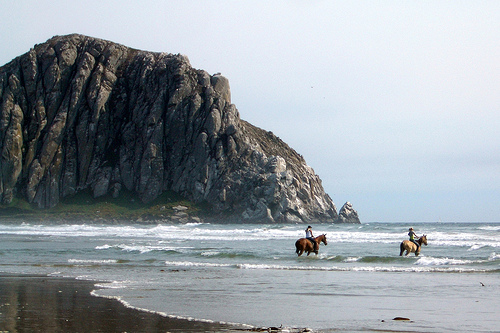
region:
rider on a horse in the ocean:
[294, 226, 326, 257]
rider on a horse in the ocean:
[398, 228, 430, 258]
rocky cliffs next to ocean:
[1, 32, 362, 221]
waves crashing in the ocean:
[11, 222, 496, 244]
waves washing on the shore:
[1, 259, 491, 331]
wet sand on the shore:
[1, 272, 278, 332]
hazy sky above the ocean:
[0, 1, 497, 223]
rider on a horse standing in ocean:
[293, 225, 328, 257]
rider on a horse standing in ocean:
[399, 226, 429, 257]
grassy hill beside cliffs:
[2, 189, 222, 226]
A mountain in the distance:
[0, 33, 361, 227]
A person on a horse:
[295, 225, 327, 257]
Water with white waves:
[0, 223, 499, 332]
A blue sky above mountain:
[0, 0, 499, 220]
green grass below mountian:
[0, 180, 208, 221]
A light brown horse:
[397, 233, 429, 256]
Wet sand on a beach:
[0, 276, 251, 332]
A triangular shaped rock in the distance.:
[339, 201, 359, 224]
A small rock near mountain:
[172, 203, 189, 211]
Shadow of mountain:
[63, 175, 185, 210]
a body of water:
[167, 188, 490, 290]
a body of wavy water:
[168, 222, 492, 325]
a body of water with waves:
[248, 231, 417, 299]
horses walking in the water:
[261, 190, 480, 330]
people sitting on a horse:
[289, 211, 483, 281]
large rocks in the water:
[118, 9, 417, 308]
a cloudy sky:
[312, 33, 466, 155]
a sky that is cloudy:
[326, 37, 496, 201]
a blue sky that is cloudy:
[304, 60, 496, 175]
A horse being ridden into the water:
[294, 223, 327, 256]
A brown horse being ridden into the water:
[397, 225, 429, 255]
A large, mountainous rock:
[2, 33, 363, 224]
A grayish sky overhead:
[3, 1, 497, 223]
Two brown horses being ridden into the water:
[294, 222, 428, 258]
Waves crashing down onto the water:
[13, 215, 495, 274]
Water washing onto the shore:
[4, 260, 268, 331]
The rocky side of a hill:
[28, 67, 155, 182]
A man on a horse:
[294, 224, 329, 257]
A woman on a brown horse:
[393, 224, 428, 258]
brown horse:
[287, 227, 326, 259]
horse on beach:
[400, 233, 433, 260]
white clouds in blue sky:
[345, 38, 427, 99]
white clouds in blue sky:
[382, 116, 414, 158]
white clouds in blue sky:
[407, 0, 455, 51]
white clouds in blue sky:
[310, 68, 348, 102]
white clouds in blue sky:
[337, 48, 379, 98]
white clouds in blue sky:
[282, 58, 319, 120]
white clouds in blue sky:
[321, 88, 363, 138]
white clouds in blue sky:
[404, 83, 444, 145]